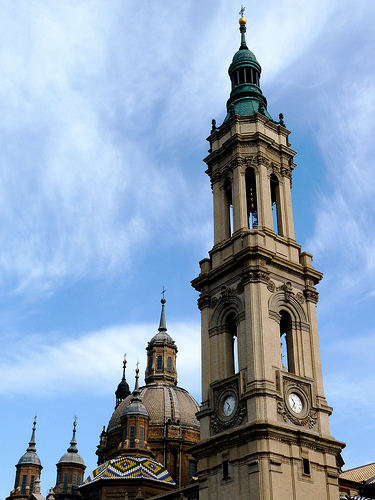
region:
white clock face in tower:
[218, 388, 242, 421]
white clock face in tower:
[284, 386, 314, 422]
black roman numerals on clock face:
[287, 390, 307, 415]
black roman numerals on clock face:
[219, 393, 239, 419]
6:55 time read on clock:
[284, 390, 306, 413]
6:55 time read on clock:
[218, 397, 235, 415]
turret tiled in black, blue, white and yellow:
[74, 354, 189, 491]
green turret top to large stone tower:
[220, 2, 273, 125]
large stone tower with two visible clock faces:
[189, 101, 350, 496]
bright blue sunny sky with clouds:
[4, 0, 366, 490]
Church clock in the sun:
[282, 386, 308, 418]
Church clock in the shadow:
[216, 390, 240, 416]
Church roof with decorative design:
[79, 453, 179, 489]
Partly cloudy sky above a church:
[0, 0, 373, 421]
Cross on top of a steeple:
[230, 1, 252, 24]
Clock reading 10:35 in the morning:
[286, 387, 307, 414]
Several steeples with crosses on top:
[12, 282, 168, 448]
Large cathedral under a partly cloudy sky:
[0, 5, 374, 498]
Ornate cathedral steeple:
[101, 280, 197, 427]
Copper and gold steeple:
[221, 3, 281, 116]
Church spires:
[6, 5, 363, 496]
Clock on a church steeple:
[274, 370, 321, 429]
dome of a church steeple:
[101, 381, 201, 440]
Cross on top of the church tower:
[236, 5, 247, 17]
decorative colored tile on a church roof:
[77, 453, 177, 488]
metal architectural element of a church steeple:
[222, 48, 276, 121]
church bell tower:
[192, 7, 352, 498]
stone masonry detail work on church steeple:
[187, 224, 324, 301]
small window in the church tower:
[297, 454, 313, 480]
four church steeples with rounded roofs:
[8, 288, 199, 495]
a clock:
[283, 388, 312, 419]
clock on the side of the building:
[215, 388, 234, 418]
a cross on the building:
[152, 281, 174, 297]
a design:
[93, 459, 159, 477]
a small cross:
[128, 359, 141, 370]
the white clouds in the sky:
[20, 177, 134, 283]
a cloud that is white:
[320, 201, 374, 257]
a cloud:
[17, 337, 98, 388]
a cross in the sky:
[66, 413, 85, 426]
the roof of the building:
[151, 389, 191, 417]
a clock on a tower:
[212, 387, 242, 437]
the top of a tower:
[193, 2, 290, 127]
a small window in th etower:
[297, 447, 318, 482]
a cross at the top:
[157, 285, 175, 331]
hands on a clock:
[284, 395, 299, 412]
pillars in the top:
[239, 160, 268, 232]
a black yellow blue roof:
[88, 456, 171, 483]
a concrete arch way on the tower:
[252, 290, 304, 418]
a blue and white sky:
[26, 94, 155, 352]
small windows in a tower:
[149, 351, 172, 382]